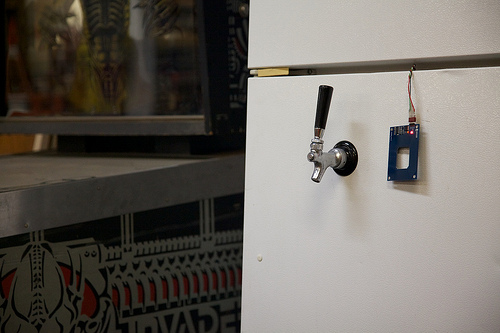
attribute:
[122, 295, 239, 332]
writing — black, white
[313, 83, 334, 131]
handle — black, slender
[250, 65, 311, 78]
hinge — yellow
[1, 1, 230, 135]
frame — black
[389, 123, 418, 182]
item — electric, blue, hanging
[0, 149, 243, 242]
countertop — silver, stainless steel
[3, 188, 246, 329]
pattern — green, black, white, red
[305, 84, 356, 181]
tap — black, silver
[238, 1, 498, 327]
front — white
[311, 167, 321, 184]
nozzle — silver